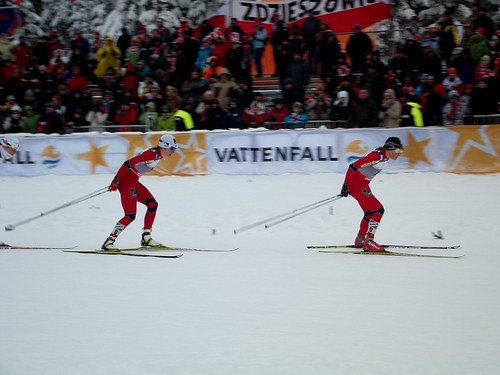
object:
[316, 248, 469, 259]
skis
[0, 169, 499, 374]
ground